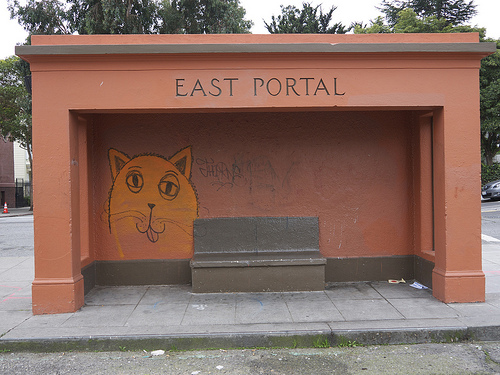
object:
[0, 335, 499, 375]
road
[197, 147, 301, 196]
graffiti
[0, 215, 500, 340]
pavement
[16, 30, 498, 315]
shelter area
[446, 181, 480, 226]
ground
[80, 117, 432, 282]
wall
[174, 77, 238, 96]
letters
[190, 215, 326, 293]
bench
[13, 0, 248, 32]
tree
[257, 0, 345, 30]
tree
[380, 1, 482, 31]
tree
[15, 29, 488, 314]
shelter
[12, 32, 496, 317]
stage shade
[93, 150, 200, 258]
graffitti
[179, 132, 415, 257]
shelter wall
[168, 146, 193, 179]
cone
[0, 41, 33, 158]
branch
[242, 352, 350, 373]
oil stain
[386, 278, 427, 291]
litter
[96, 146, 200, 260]
cat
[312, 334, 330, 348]
grass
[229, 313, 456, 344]
curb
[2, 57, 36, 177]
tree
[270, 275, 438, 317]
ground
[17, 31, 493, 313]
building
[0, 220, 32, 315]
sidewalk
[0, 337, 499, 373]
concrete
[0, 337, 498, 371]
street